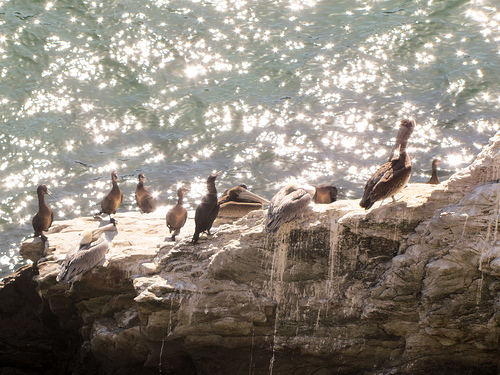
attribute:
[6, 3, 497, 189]
water — green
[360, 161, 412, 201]
body — brown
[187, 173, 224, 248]
bird — black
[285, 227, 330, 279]
stain — black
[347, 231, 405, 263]
stain — black